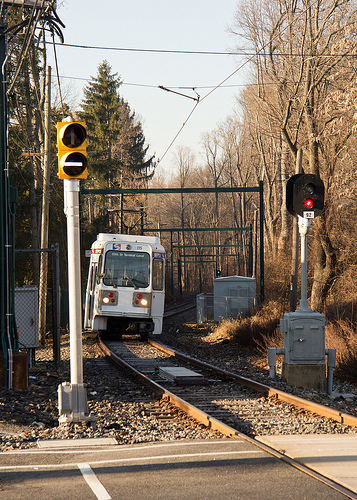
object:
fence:
[197, 293, 257, 330]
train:
[77, 233, 167, 342]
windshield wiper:
[123, 265, 137, 290]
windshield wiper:
[107, 264, 117, 287]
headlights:
[99, 290, 151, 308]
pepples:
[0, 331, 357, 451]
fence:
[7, 243, 61, 366]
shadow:
[79, 461, 166, 473]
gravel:
[0, 307, 357, 453]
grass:
[199, 247, 357, 382]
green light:
[217, 270, 220, 274]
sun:
[122, 334, 175, 360]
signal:
[286, 173, 325, 220]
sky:
[30, 0, 302, 190]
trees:
[225, 0, 357, 313]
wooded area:
[0, 0, 357, 376]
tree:
[73, 59, 161, 235]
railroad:
[95, 296, 357, 500]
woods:
[0, 0, 357, 313]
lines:
[76, 464, 111, 500]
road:
[0, 435, 357, 500]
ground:
[0, 296, 357, 500]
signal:
[57, 121, 88, 179]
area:
[0, 0, 357, 500]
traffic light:
[56, 115, 99, 425]